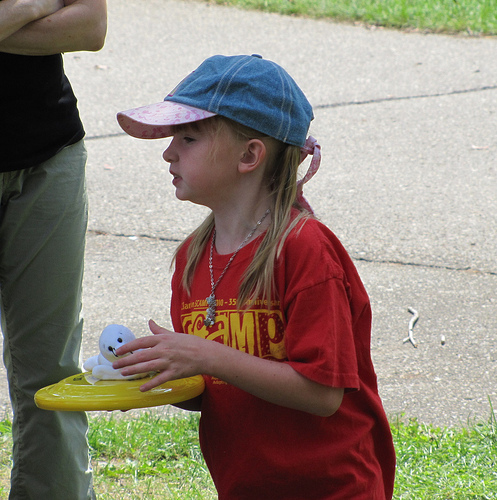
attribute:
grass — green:
[409, 438, 480, 491]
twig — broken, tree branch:
[402, 305, 421, 350]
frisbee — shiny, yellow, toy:
[39, 366, 204, 410]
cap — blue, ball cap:
[117, 54, 313, 150]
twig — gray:
[397, 288, 432, 359]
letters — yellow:
[174, 296, 307, 391]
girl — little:
[80, 46, 436, 482]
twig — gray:
[397, 293, 427, 377]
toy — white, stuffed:
[81, 320, 164, 383]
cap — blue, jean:
[109, 48, 322, 164]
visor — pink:
[113, 96, 218, 144]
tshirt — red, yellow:
[171, 208, 394, 496]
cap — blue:
[100, 42, 362, 157]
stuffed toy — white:
[79, 320, 143, 384]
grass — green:
[1, 406, 496, 496]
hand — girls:
[111, 318, 210, 391]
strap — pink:
[293, 134, 326, 200]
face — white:
[101, 332, 132, 357]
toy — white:
[71, 306, 156, 387]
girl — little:
[95, 50, 398, 498]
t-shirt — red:
[162, 206, 398, 496]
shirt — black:
[0, 49, 85, 172]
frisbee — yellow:
[19, 328, 215, 413]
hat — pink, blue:
[136, 56, 328, 143]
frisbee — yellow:
[32, 372, 221, 423]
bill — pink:
[109, 96, 221, 144]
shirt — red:
[163, 191, 403, 499]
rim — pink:
[116, 100, 216, 139]